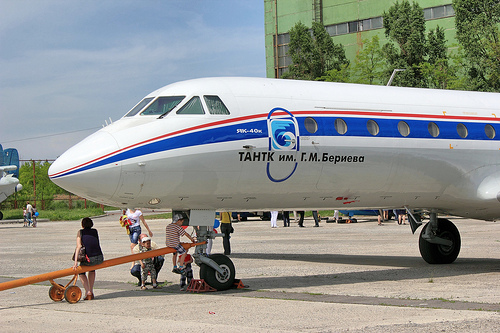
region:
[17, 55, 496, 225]
white and blue airplane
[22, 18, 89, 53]
white clouds in blue sky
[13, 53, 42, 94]
white clouds in blue sky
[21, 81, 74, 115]
white clouds in blue sky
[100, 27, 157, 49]
white clouds in blue sky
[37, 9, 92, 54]
white clouds in blue sky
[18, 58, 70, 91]
white clouds in blue sky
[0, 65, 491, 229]
red white and blue plane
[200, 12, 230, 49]
white clouds in blue sky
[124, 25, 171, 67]
white clouds in blue sky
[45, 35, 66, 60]
white clouds in blue sky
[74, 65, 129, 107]
white clouds in blue sky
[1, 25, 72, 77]
white clouds in blue sky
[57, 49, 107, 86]
white clouds in blue sky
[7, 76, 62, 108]
white clouds in blue sky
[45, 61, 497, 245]
blue and white plane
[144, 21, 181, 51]
white clouds in blue sky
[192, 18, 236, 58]
white clouds in blue sky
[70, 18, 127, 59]
white clouds in blue sky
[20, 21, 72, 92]
white clouds in blue sky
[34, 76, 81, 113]
white clouds in blue sky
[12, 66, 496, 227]
white and blue plane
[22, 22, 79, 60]
white clouds in blue sky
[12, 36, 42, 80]
white clouds in blue sky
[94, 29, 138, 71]
white clouds in blue sky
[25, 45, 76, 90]
white clouds in blue sky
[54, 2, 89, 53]
white clouds in blue sky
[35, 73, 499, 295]
white airplane with blue stripes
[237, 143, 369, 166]
black writing on white airplane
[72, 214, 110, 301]
woman standing with blue sleeveless shirt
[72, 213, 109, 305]
woman standing with blue shorts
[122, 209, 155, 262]
woman walking with white shirt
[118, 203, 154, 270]
woman walking with denim shorts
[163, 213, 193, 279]
boy wearing backwards baseball cap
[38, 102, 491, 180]
blue and red plane stripes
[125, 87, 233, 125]
Front windows of an airplane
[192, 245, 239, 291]
A black round plane wheel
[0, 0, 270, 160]
White clouds in the sky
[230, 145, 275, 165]
"TAHTK" written on side of plane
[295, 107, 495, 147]
Seven small and round plane windows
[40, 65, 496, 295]
A big white airplane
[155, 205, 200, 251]
Person wearing a striped shirt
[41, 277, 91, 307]
Two round orange wheels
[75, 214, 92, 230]
the hair of a woman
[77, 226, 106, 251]
the shirt of a woman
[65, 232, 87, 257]
the left arm of a woman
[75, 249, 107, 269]
the shorts of a woman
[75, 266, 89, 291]
the left leg of a woman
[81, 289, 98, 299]
the shoes of a woman